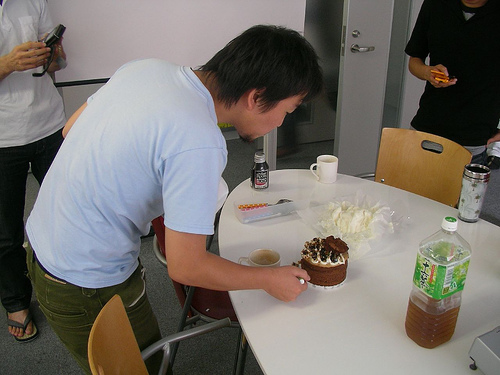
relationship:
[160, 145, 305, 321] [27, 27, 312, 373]
arm of a man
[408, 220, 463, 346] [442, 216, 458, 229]
bottle has a cap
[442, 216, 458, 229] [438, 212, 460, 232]
cap of a cap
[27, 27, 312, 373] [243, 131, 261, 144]
man has a beard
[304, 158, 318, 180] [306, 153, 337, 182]
handle of a cup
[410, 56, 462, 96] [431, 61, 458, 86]
hand holding phone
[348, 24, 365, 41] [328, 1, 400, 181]
lock on door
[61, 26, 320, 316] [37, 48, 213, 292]
man wearing a white shirt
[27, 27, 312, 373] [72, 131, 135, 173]
man wears pants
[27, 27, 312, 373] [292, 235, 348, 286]
man having cake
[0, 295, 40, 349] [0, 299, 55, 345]
foot wearing flip flops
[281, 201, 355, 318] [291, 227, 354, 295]
hand cutting a cake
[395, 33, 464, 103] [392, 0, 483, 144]
hand of a man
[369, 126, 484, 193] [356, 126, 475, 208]
back of a chair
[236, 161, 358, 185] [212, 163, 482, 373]
tip of a table